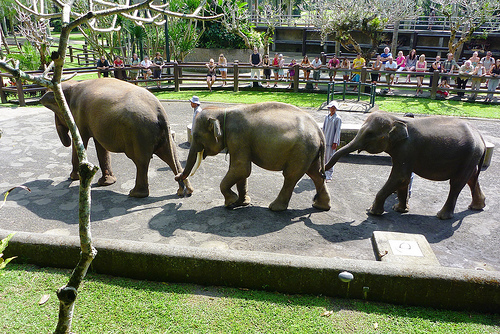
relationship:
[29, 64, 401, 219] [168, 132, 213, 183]
elephant with tusk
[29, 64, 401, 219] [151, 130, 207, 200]
elephant has trunk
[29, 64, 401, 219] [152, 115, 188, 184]
elephant has tail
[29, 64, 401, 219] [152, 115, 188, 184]
elephant have tail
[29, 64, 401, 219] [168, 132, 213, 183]
elephant has tusk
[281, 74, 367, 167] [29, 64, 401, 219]
man in charge of elephant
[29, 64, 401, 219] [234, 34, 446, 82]
elephant and visitor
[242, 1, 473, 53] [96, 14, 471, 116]
building in background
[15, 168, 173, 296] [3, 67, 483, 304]
tree next to enclosure